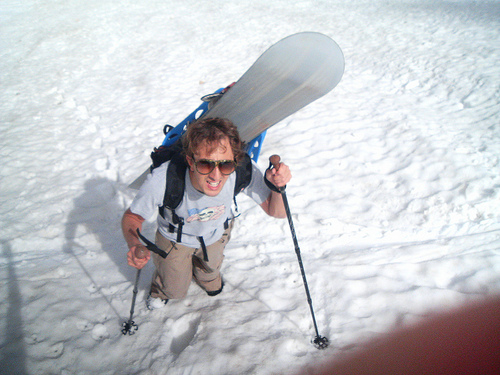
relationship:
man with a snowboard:
[117, 28, 346, 353] [230, 26, 344, 122]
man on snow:
[117, 28, 346, 353] [389, 42, 464, 147]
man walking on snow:
[117, 28, 346, 353] [389, 42, 464, 147]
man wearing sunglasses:
[117, 28, 346, 353] [196, 154, 237, 176]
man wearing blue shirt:
[117, 28, 346, 353] [167, 198, 239, 243]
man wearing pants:
[117, 28, 346, 353] [159, 240, 224, 299]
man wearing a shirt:
[117, 28, 346, 353] [167, 198, 239, 243]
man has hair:
[117, 28, 346, 353] [189, 129, 217, 148]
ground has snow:
[393, 176, 430, 238] [389, 42, 464, 147]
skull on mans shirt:
[195, 207, 220, 228] [167, 198, 239, 243]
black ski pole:
[285, 207, 297, 234] [283, 187, 331, 351]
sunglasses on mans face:
[196, 154, 237, 176] [195, 143, 233, 196]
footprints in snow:
[395, 181, 499, 242] [389, 42, 464, 147]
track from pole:
[316, 309, 337, 331] [283, 187, 331, 351]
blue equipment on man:
[167, 131, 180, 142] [121, 113, 294, 309]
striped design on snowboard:
[269, 56, 327, 95] [230, 26, 344, 122]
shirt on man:
[167, 198, 239, 243] [117, 28, 346, 353]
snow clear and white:
[389, 42, 464, 147] [86, 63, 134, 101]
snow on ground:
[389, 42, 464, 147] [393, 176, 430, 238]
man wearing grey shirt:
[117, 28, 346, 353] [167, 198, 239, 243]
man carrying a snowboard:
[117, 28, 346, 353] [230, 26, 344, 122]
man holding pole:
[117, 28, 346, 353] [283, 187, 331, 351]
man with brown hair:
[117, 28, 346, 353] [189, 129, 217, 148]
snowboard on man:
[230, 26, 344, 122] [117, 28, 346, 353]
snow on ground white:
[389, 42, 464, 147] [86, 63, 134, 101]